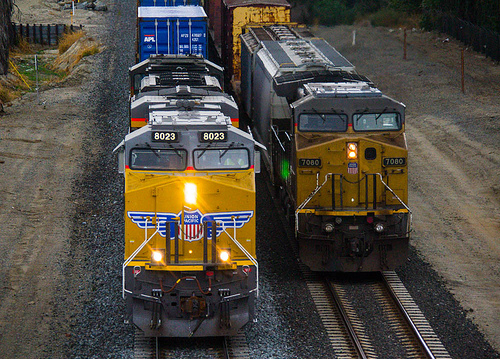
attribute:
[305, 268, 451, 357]
tracks — train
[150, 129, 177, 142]
numbers — white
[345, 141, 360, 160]
train light — duel, middle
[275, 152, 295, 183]
light — green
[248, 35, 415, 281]
car — yellow, grey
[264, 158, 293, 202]
ground — yellow, fronts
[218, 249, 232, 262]
light — small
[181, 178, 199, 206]
light — large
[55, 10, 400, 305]
train — top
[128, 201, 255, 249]
logo — union pacific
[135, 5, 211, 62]
containers — blue, yellow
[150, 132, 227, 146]
numbers — white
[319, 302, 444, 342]
train tracks — metal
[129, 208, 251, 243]
logo — white, red, blue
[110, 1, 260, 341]
train — yellow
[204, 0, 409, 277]
train — yellow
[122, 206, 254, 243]
logo — red, white, blue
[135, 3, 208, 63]
container — apl, blue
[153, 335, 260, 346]
tracks — brown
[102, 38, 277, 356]
engines — train